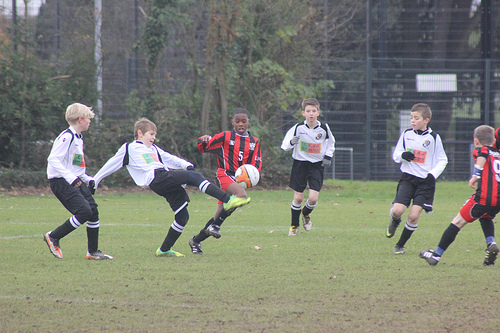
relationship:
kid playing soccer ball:
[120, 122, 249, 255] [233, 163, 261, 189]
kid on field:
[120, 122, 249, 255] [4, 190, 500, 332]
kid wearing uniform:
[120, 122, 249, 255] [111, 144, 226, 227]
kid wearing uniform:
[39, 111, 113, 250] [54, 134, 102, 233]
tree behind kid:
[140, 11, 296, 189] [120, 122, 249, 255]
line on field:
[104, 211, 472, 245] [4, 190, 500, 332]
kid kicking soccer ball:
[120, 122, 249, 255] [233, 163, 261, 189]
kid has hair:
[39, 111, 113, 250] [66, 99, 94, 123]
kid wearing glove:
[39, 111, 113, 250] [87, 181, 95, 188]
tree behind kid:
[140, 11, 296, 189] [201, 107, 261, 258]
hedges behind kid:
[6, 169, 54, 190] [39, 111, 113, 250]